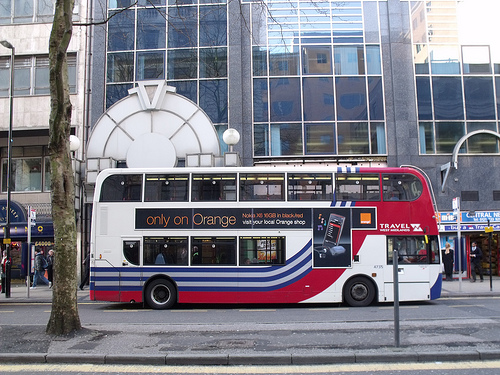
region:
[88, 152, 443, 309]
bus on the road.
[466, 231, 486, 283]
Man walking on the side walk.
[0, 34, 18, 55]
Light above the street.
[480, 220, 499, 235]
Yellow sign on the pole.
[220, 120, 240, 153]
Light on the building.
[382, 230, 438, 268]
window on the bus.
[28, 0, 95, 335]
Tree trunk in by the road.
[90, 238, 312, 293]
blue stripes on the bus.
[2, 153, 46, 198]
Window in the building.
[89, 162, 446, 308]
a red white and blue double decker bus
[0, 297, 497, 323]
a paved city street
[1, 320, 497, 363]
a city street median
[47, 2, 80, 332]
a tall tree trunk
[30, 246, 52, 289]
a person walking on sidewalk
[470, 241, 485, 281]
a person walking on sidewalk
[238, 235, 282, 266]
a bus passenger window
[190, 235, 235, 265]
a bus passenger window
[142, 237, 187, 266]
a bus passenger window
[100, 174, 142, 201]
a bus passenger window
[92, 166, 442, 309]
red white and blue bus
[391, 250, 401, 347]
grey metal pole in ground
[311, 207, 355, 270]
black sign on bus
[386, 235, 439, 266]
side window on bus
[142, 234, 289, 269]
windows on side of bus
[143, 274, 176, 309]
black tire on bus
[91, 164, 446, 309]
double decker bus on road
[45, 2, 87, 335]
brown wood tree trunk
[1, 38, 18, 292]
grey metal lamp post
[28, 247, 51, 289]
person walking on sidewalk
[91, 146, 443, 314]
bus with upper and lower levels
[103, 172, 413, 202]
upper level of bus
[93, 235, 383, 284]
lower level of bus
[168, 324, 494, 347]
sidewalk on the street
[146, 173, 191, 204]
window on upper level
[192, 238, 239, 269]
window on lower level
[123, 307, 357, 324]
street where vehicles travel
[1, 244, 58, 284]
pedestrians on the sidewalk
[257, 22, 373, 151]
window on a building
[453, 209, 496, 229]
lettering on the building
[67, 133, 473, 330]
a double decker bus in the city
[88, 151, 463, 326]
the double decker bus is red, white and blue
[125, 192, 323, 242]
an advertisement on the bus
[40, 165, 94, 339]
a tree in the area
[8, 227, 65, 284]
people on the street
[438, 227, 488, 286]
pedestrians in the background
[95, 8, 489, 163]
a gray building in the area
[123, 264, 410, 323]
the wheels on the bus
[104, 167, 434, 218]
the bus windows are tinted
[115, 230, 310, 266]
passengers can be seen in the window